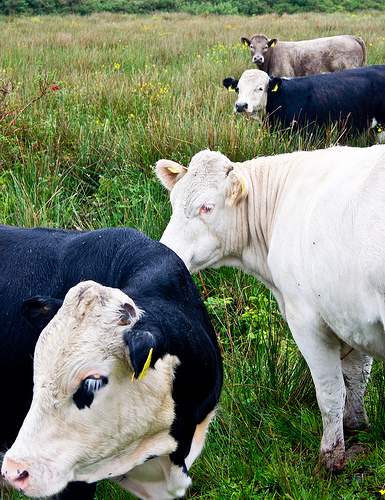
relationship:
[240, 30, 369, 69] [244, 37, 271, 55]
cow has eye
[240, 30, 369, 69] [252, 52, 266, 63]
cow has nose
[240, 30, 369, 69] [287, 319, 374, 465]
cow has legs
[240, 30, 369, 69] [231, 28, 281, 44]
cow has ear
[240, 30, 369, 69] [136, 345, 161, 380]
cow has tag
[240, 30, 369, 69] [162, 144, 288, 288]
cow has neck